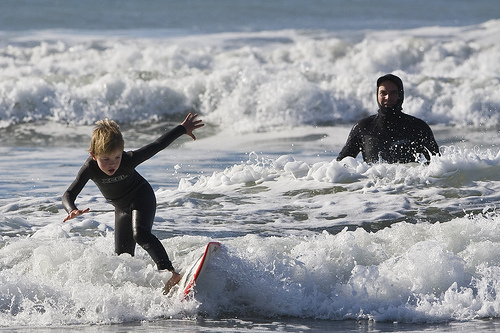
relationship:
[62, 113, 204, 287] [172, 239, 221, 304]
boy trying to balance on surfboard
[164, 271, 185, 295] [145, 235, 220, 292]
foot on surfboard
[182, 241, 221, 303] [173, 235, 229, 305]
edge on surfboard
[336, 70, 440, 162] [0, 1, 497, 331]
man in water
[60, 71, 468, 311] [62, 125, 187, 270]
man/child in swimsuit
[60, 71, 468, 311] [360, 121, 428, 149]
man/child in wetsuit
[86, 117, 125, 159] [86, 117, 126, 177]
brown hair on head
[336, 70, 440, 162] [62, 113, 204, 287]
man watching boy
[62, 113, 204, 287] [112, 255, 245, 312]
boy riding surfboard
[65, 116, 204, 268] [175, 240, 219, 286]
boy riding surfboard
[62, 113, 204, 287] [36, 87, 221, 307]
boy wearing swimsuit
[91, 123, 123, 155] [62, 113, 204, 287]
brown hair on boy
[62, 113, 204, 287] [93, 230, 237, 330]
boy on surfboard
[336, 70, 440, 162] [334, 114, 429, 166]
man wearing wetsuit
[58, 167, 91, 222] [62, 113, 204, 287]
arm on boy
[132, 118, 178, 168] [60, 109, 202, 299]
left arm on boy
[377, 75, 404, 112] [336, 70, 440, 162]
head on man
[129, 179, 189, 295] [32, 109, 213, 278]
leg on boy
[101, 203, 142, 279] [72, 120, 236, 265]
leg on boy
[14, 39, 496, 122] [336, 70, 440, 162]
wave behind man